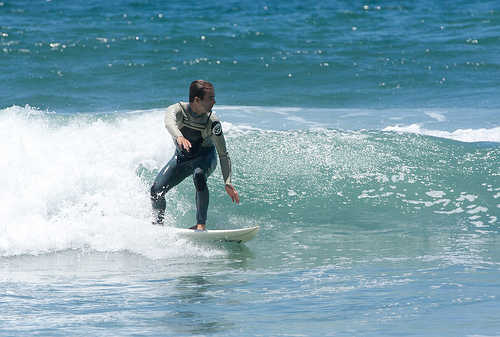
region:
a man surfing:
[44, 37, 286, 284]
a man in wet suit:
[122, 52, 334, 318]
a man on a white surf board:
[105, 43, 322, 335]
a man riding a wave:
[55, 57, 361, 294]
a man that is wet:
[73, 23, 284, 273]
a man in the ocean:
[98, 37, 318, 284]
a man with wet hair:
[93, 33, 300, 271]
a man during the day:
[124, 42, 310, 305]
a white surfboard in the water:
[137, 206, 305, 261]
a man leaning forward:
[111, 38, 309, 323]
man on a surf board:
[129, 71, 284, 283]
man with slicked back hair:
[121, 68, 273, 263]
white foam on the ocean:
[32, 84, 91, 269]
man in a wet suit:
[132, 78, 269, 245]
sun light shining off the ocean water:
[321, 74, 420, 217]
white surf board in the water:
[120, 208, 273, 250]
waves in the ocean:
[82, 21, 132, 70]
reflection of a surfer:
[151, 234, 248, 328]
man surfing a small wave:
[141, 68, 271, 255]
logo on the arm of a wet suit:
[210, 121, 228, 139]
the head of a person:
[186, 77, 221, 114]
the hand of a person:
[208, 120, 253, 215]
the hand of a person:
[162, 101, 199, 155]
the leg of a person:
[190, 165, 224, 230]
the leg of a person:
[148, 160, 187, 227]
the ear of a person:
[190, 94, 205, 106]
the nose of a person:
[211, 98, 218, 105]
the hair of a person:
[187, 76, 210, 104]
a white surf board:
[153, 209, 271, 246]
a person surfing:
[131, 53, 262, 263]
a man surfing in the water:
[135, 46, 292, 326]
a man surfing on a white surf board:
[132, 39, 328, 306]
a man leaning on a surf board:
[155, 61, 264, 276]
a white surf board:
[127, 208, 252, 251]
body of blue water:
[35, 24, 487, 297]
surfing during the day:
[67, 38, 340, 275]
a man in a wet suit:
[106, 40, 319, 280]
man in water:
[149, 68, 241, 227]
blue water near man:
[305, 150, 436, 285]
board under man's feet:
[130, 211, 255, 261]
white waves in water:
[35, 135, 130, 225]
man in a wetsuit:
[110, 75, 271, 265]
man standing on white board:
[100, 51, 275, 262]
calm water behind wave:
[250, 31, 381, 116]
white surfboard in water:
[113, 216, 251, 272]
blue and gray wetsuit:
[102, 91, 251, 251]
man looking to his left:
[167, 73, 245, 133]